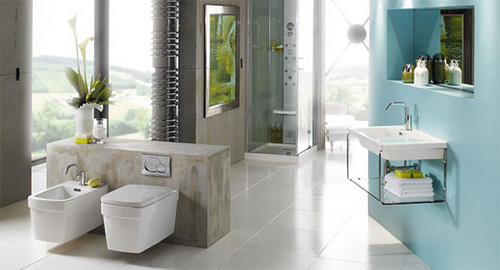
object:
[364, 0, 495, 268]
wall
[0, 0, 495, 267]
bathroom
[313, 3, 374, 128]
window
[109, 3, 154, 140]
window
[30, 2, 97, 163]
window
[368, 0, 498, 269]
blue wall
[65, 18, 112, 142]
plant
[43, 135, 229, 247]
island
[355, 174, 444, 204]
ground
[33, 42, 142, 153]
countryside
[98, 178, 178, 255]
toilet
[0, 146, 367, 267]
tiles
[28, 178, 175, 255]
deep toilet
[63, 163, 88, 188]
silver faucet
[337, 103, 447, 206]
sink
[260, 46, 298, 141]
shelf shower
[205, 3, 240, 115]
picture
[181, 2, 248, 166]
wall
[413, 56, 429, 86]
bottle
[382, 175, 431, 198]
towel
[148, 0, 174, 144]
pole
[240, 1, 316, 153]
shower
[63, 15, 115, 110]
plant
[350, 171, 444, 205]
shelf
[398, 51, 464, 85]
toiletries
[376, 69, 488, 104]
shelf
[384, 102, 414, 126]
faucet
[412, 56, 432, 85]
lotion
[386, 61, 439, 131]
lotion